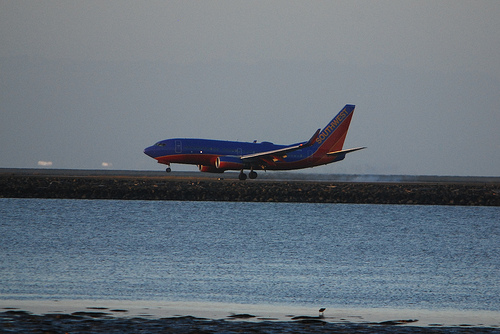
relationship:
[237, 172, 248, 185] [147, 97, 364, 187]
wheel on plane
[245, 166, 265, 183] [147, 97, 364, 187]
wheel on plane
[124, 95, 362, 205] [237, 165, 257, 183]
airplane has wheel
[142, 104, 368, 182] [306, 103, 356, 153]
airplane has tail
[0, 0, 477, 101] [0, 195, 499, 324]
sky above water